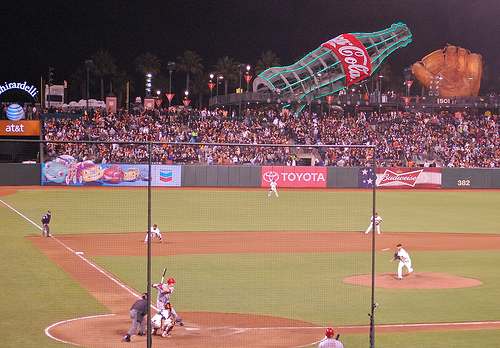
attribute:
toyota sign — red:
[262, 166, 324, 185]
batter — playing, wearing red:
[151, 270, 186, 300]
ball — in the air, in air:
[378, 245, 389, 257]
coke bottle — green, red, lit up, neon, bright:
[253, 29, 402, 91]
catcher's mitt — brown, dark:
[175, 315, 183, 326]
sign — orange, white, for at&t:
[2, 120, 39, 139]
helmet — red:
[168, 274, 176, 284]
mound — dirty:
[377, 267, 417, 299]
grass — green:
[142, 197, 196, 214]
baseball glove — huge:
[417, 42, 489, 104]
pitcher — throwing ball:
[389, 243, 416, 270]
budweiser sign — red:
[364, 167, 442, 187]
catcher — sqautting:
[157, 308, 171, 335]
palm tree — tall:
[135, 49, 161, 84]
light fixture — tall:
[235, 55, 257, 78]